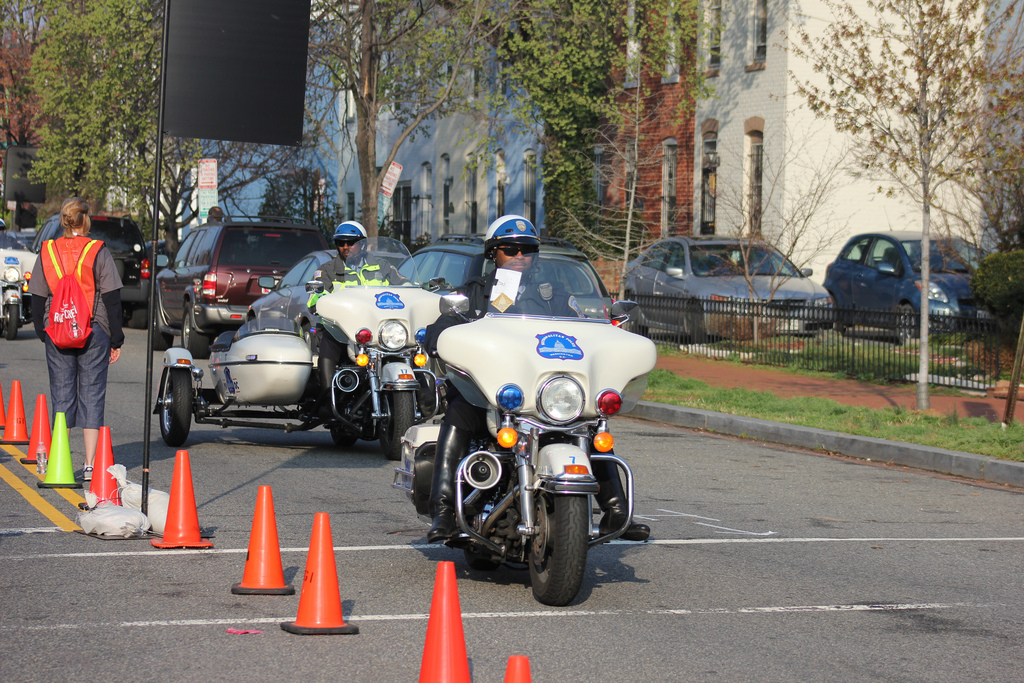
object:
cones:
[144, 441, 221, 554]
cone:
[0, 377, 32, 446]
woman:
[25, 196, 129, 483]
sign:
[165, 0, 316, 145]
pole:
[136, 0, 178, 534]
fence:
[605, 289, 1005, 392]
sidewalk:
[657, 355, 1023, 431]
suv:
[141, 216, 341, 360]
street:
[651, 467, 1024, 683]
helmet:
[480, 211, 543, 265]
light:
[495, 382, 527, 412]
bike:
[389, 310, 651, 609]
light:
[595, 388, 626, 419]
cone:
[16, 392, 55, 465]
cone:
[32, 407, 85, 493]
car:
[620, 234, 837, 346]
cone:
[76, 423, 129, 515]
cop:
[421, 210, 653, 550]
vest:
[27, 235, 126, 336]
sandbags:
[73, 487, 152, 543]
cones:
[228, 481, 299, 596]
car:
[817, 227, 1005, 345]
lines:
[0, 536, 1024, 563]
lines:
[621, 603, 978, 616]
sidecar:
[209, 314, 318, 407]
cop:
[304, 217, 428, 430]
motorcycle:
[152, 229, 469, 461]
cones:
[277, 506, 365, 637]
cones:
[405, 554, 490, 682]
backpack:
[41, 273, 96, 352]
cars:
[0, 218, 43, 342]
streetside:
[0, 157, 671, 367]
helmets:
[328, 218, 370, 259]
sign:
[145, 27, 388, 174]